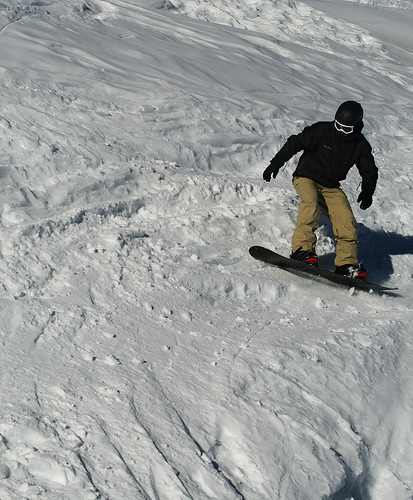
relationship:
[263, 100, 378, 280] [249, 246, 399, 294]
man on snowboard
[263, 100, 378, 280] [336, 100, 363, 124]
man wears hat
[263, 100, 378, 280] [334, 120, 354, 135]
man wearing goggles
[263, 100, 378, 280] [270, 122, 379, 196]
man wears coat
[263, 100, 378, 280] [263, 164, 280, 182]
man wears glove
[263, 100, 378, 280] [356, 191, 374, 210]
man wears glove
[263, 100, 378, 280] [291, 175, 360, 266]
man wears pants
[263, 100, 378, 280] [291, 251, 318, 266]
man wears shoe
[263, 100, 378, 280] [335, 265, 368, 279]
man wears shoe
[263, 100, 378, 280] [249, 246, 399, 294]
man has snowboard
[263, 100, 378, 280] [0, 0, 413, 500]
man snowboard down hill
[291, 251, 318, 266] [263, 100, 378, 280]
shoe of man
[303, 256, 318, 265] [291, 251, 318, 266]
bottom of shoe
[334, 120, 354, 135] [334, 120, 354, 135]
goggles with goggles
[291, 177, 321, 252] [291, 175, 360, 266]
leg of pants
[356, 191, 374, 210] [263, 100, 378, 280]
glove of man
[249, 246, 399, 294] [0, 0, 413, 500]
snowboard on top of snow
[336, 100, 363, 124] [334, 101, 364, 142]
hat on top of head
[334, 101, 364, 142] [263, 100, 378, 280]
head of man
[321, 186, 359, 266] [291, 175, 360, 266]
leg with pants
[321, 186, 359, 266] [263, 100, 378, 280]
leg of man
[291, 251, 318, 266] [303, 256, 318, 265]
shoe with bottom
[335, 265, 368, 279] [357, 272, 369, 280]
shoe with bottom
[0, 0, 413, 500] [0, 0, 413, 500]
hill of snow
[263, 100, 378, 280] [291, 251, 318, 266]
man wearing shoe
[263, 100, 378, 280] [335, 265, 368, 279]
man wearing shoe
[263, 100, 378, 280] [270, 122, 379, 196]
man wearing coat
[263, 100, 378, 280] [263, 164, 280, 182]
man wearing glove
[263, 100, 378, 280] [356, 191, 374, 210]
man wearing glove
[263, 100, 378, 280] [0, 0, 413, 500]
man in snow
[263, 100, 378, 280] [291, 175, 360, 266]
man wearing pants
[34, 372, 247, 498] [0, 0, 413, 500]
tracks in snow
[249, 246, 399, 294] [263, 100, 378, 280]
snowboard under man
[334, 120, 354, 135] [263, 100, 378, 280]
goggles on face of man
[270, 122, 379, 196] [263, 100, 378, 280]
coat on man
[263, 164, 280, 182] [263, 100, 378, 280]
glove on man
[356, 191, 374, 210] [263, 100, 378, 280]
glove on man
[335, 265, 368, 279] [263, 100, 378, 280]
shoe of man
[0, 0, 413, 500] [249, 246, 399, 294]
snow under snowboard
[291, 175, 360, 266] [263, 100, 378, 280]
pants on man